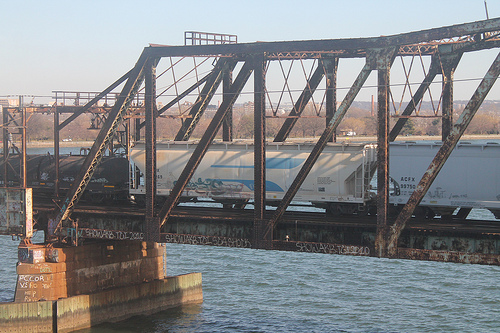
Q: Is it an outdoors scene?
A: Yes, it is outdoors.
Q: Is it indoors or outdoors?
A: It is outdoors.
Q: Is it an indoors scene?
A: No, it is outdoors.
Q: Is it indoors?
A: No, it is outdoors.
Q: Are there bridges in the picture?
A: Yes, there is a bridge.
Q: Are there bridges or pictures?
A: Yes, there is a bridge.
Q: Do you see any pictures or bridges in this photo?
A: Yes, there is a bridge.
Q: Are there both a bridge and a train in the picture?
A: Yes, there are both a bridge and a train.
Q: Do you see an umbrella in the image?
A: No, there are no umbrellas.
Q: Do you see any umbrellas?
A: No, there are no umbrellas.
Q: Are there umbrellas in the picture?
A: No, there are no umbrellas.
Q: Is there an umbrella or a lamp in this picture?
A: No, there are no umbrellas or lamps.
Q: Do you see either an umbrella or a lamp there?
A: No, there are no umbrellas or lamps.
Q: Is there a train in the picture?
A: Yes, there is a train.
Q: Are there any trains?
A: Yes, there is a train.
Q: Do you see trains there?
A: Yes, there is a train.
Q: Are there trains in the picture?
A: Yes, there is a train.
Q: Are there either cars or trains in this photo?
A: Yes, there is a train.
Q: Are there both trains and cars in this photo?
A: Yes, there are both a train and a car.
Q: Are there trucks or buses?
A: No, there are no buses or trucks.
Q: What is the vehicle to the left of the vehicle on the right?
A: The vehicle is a train.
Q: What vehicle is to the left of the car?
A: The vehicle is a train.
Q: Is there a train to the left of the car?
A: Yes, there is a train to the left of the car.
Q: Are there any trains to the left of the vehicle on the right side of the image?
A: Yes, there is a train to the left of the car.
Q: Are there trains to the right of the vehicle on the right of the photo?
A: No, the train is to the left of the car.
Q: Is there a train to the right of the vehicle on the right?
A: No, the train is to the left of the car.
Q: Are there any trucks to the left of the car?
A: No, there is a train to the left of the car.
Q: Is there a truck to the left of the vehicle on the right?
A: No, there is a train to the left of the car.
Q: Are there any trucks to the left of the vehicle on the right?
A: No, there is a train to the left of the car.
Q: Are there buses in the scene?
A: No, there are no buses.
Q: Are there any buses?
A: No, there are no buses.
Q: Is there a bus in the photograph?
A: No, there are no buses.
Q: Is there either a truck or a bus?
A: No, there are no buses or trucks.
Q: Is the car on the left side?
A: No, the car is on the right of the image.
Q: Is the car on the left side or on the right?
A: The car is on the right of the image.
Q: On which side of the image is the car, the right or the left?
A: The car is on the right of the image.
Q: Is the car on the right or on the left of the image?
A: The car is on the right of the image.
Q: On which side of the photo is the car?
A: The car is on the right of the image.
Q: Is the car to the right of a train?
A: Yes, the car is to the right of a train.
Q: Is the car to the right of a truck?
A: No, the car is to the right of a train.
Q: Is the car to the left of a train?
A: No, the car is to the right of a train.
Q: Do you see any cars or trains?
A: Yes, there is a train.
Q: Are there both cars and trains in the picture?
A: Yes, there are both a train and a car.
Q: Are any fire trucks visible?
A: No, there are no fire trucks.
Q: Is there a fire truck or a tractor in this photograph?
A: No, there are no fire trucks or tractors.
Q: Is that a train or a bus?
A: That is a train.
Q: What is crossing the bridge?
A: The train is crossing the bridge.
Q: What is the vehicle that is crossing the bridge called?
A: The vehicle is a train.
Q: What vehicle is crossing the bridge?
A: The vehicle is a train.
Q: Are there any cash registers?
A: No, there are no cash registers.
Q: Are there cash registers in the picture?
A: No, there are no cash registers.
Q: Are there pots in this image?
A: No, there are no pots.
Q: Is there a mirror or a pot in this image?
A: No, there are no pots or mirrors.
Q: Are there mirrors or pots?
A: No, there are no pots or mirrors.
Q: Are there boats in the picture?
A: No, there are no boats.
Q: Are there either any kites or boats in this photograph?
A: No, there are no boats or kites.